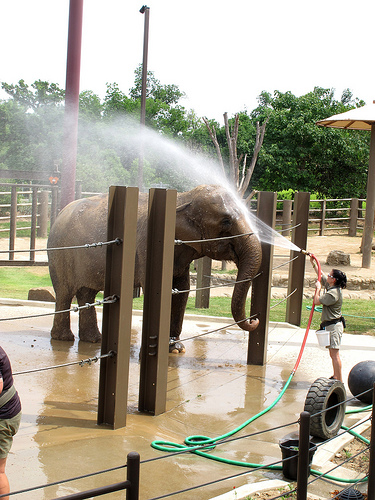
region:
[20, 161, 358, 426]
An elephant in an enclosure.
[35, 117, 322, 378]
An elephant being sprayed with water.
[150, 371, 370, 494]
A long green water hose.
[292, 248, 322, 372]
Red section of a water hose.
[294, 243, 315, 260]
Nozzle at end of water hose.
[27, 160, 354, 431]
Woman spraying an elephant with a water hose.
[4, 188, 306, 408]
Section of fence made with cables.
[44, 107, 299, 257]
Water spraying on the elephant.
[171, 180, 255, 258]
The head of an elephant.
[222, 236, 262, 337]
The trunk of an elephant.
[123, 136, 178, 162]
water in the air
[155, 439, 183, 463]
a water hose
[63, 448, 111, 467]
a shadow on the ground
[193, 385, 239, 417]
the water on the ground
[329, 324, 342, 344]
shorts the lady is wearing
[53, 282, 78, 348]
the back leg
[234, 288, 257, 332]
the trunk on the elephant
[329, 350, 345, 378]
the womens legs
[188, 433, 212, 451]
the hose is green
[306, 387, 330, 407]
a black tire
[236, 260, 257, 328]
trunk of the elephant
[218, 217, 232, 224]
eye of the elephant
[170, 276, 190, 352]
front leg of the elephant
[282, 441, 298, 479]
black color bucket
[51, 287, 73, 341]
back leg of elephant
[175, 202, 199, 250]
ear of the elephant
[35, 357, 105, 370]
rope tied to erected pillar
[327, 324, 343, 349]
woman wearing shorts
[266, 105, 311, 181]
trees visible at background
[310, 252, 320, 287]
woman holding red color pipe in her hands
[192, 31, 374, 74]
white sky with clouds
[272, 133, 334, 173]
tree with branches and leaves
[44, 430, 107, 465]
water that's fallen on the ground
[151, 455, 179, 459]
wire fence to set boundaries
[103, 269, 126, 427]
metal post for holding wire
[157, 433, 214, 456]
water hose on ground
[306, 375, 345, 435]
large black rubber tire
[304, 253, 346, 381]
zoo keeper holding water hose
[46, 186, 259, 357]
elephant being sprayed with water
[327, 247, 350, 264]
large rock for a touch of naturalness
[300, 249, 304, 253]
A water sprinkler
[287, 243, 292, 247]
A jet of water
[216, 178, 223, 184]
Water bouncing off the head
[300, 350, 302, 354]
A red hose pipe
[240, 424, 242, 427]
A green hose pipe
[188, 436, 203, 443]
A coiled house pipe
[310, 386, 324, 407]
A vehicle tire standing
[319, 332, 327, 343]
A white bucket on the side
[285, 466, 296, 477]
A black bucket on the ground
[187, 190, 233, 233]
An elephant taking a shower